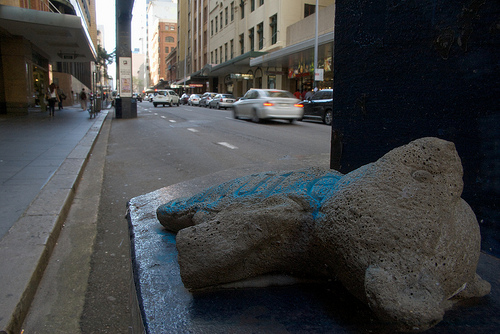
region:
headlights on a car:
[254, 98, 313, 115]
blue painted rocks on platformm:
[137, 158, 347, 274]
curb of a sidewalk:
[29, 111, 115, 321]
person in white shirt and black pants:
[39, 77, 69, 127]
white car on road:
[218, 78, 302, 158]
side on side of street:
[81, 49, 145, 169]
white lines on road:
[154, 90, 244, 158]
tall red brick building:
[143, 25, 199, 100]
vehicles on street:
[62, 69, 314, 142]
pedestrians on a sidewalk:
[4, 68, 108, 121]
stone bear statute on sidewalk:
[158, 141, 497, 326]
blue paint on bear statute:
[157, 164, 331, 220]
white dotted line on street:
[135, 89, 236, 163]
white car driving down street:
[229, 82, 304, 119]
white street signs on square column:
[113, 56, 131, 97]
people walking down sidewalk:
[44, 79, 88, 109]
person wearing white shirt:
[47, 81, 58, 111]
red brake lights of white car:
[256, 94, 303, 115]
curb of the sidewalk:
[18, 100, 125, 325]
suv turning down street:
[143, 84, 180, 106]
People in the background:
[41, 70, 94, 123]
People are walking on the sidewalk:
[35, 72, 90, 122]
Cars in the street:
[147, 72, 334, 135]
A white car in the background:
[227, 80, 308, 130]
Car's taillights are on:
[254, 87, 304, 122]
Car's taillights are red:
[256, 91, 308, 123]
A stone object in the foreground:
[146, 128, 495, 333]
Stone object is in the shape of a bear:
[139, 118, 499, 330]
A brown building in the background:
[153, 13, 178, 80]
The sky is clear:
[96, 1, 179, 78]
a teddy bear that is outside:
[74, 50, 497, 280]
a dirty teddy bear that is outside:
[122, 115, 492, 310]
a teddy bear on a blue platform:
[64, 40, 494, 291]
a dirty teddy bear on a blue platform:
[109, 27, 486, 328]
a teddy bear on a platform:
[97, 62, 492, 332]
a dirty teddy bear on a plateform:
[94, 68, 486, 312]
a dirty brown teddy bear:
[104, 80, 499, 305]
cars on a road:
[129, 18, 392, 205]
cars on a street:
[122, 26, 336, 178]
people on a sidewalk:
[0, 37, 180, 136]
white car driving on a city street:
[233, 86, 305, 122]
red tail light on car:
[264, 101, 272, 106]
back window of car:
[263, 89, 292, 98]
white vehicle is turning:
[152, 87, 182, 107]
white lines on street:
[217, 139, 237, 153]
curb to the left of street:
[5, 105, 110, 332]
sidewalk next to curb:
[1, 100, 88, 278]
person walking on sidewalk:
[47, 81, 56, 113]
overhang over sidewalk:
[3, 8, 98, 67]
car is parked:
[205, 91, 237, 108]